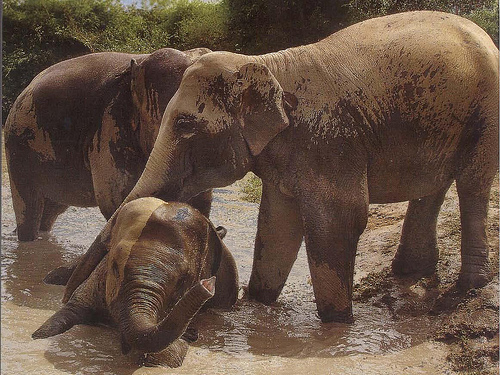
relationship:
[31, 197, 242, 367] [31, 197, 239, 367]
bath getting a bath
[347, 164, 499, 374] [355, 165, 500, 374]
mud has tracks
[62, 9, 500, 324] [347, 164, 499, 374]
elephant has legs on mud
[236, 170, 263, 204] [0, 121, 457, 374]
grass near water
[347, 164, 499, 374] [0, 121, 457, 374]
mud near water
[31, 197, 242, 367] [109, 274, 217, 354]
bath has a trunk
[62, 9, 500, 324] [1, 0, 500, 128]
elephant in front of trees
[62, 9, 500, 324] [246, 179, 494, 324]
elephant has four legs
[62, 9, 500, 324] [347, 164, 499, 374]
elephant standing in mud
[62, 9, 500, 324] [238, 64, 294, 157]
elephant has an ear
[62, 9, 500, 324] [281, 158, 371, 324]
elephant has a leg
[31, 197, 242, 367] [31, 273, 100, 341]
bath has a leg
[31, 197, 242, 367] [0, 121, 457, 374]
bath in water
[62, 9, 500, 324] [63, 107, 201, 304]
elephant has a trunk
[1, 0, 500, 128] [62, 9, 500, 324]
trees behind elephant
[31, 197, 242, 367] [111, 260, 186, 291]
bath has eyes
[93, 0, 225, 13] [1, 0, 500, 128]
sky behind trees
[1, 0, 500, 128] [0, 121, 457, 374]
trees near water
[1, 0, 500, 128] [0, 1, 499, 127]
trees have leaves